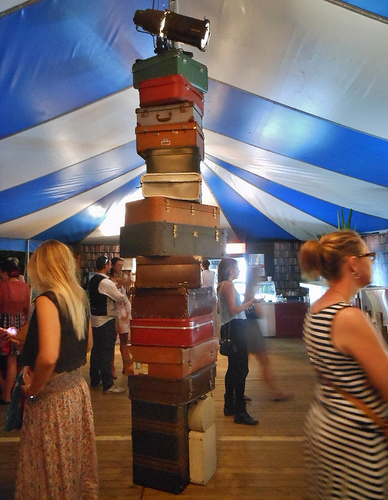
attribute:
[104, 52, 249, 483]
suitcase — stack, several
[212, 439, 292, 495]
floor — wooden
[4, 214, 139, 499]
woman — wearing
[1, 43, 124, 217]
tent — blue, white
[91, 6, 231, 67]
light — large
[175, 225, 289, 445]
person — standing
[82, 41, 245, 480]
luggage — stack, piece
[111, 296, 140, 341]
dress — white, stripes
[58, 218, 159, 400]
man — wearing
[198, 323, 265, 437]
pant — black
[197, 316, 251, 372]
purse — brown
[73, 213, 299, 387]
people — some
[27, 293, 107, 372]
coat — black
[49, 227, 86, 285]
hair — blonde, long, back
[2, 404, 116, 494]
blouse — pink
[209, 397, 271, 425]
shoe — black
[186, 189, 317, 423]
lady — light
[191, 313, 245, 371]
bag — black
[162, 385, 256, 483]
box — metallic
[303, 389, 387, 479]
stripe — black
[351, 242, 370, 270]
glass — black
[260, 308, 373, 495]
strap — across